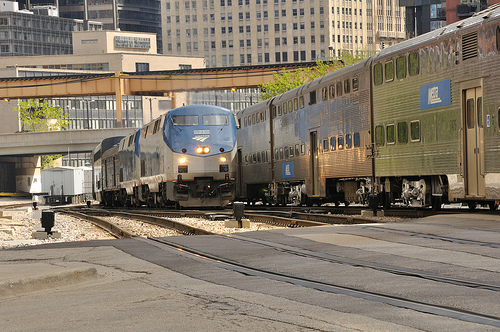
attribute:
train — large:
[123, 119, 227, 221]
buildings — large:
[58, 11, 299, 154]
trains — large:
[137, 96, 447, 256]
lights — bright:
[178, 138, 214, 166]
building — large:
[158, 9, 378, 69]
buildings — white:
[39, 127, 125, 261]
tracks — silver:
[104, 203, 334, 248]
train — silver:
[268, 38, 388, 187]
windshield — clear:
[173, 103, 253, 161]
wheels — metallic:
[101, 152, 442, 218]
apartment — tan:
[192, 20, 361, 89]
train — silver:
[122, 91, 247, 191]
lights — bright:
[192, 133, 231, 179]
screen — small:
[322, 105, 370, 168]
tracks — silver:
[86, 183, 403, 329]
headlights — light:
[158, 120, 217, 174]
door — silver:
[442, 94, 494, 179]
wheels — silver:
[378, 169, 428, 210]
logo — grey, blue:
[406, 63, 468, 133]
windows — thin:
[184, 115, 228, 143]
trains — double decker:
[266, 18, 485, 206]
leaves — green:
[19, 91, 74, 141]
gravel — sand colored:
[68, 212, 88, 245]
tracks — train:
[90, 203, 229, 264]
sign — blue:
[405, 65, 474, 130]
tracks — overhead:
[10, 52, 313, 115]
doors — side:
[448, 66, 485, 181]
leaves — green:
[264, 66, 382, 102]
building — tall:
[196, 11, 329, 74]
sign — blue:
[407, 78, 459, 128]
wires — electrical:
[7, 57, 128, 124]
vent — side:
[444, 33, 484, 70]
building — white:
[20, 145, 106, 207]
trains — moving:
[113, 55, 484, 255]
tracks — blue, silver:
[257, 193, 448, 319]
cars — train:
[296, 61, 477, 191]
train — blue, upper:
[126, 85, 327, 214]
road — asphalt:
[98, 233, 311, 330]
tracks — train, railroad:
[193, 223, 399, 320]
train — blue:
[98, 134, 171, 244]